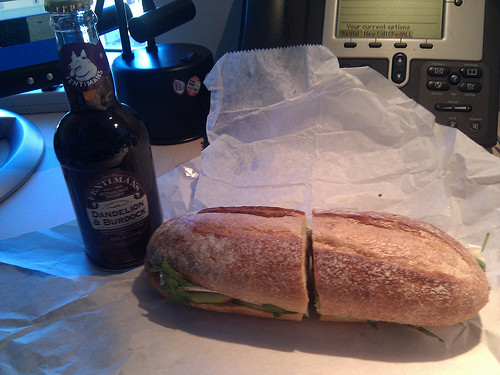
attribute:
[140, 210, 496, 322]
sandwich — brown, white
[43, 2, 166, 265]
bottle — brown, glass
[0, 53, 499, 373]
wrapper — white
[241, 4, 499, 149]
phone — black, silver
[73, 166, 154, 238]
label — brown, white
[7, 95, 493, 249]
desk — white, brown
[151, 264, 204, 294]
lettuce — green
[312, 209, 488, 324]
bread — light brown, toasted